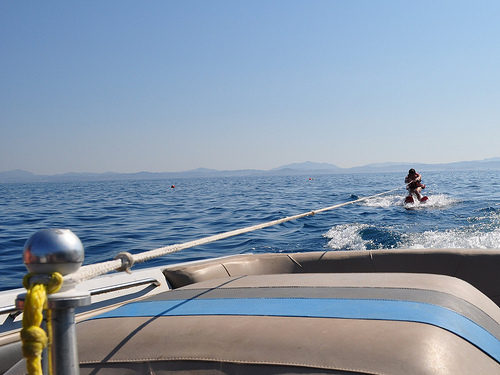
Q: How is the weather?
A: It is clear.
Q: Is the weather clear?
A: Yes, it is clear.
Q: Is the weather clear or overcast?
A: It is clear.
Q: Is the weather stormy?
A: No, it is clear.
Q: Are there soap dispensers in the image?
A: No, there are no soap dispensers.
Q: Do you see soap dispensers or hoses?
A: No, there are no soap dispensers or hoses.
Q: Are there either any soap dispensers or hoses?
A: No, there are no soap dispensers or hoses.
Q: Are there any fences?
A: No, there are no fences.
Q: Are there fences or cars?
A: No, there are no fences or cars.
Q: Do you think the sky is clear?
A: Yes, the sky is clear.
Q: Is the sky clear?
A: Yes, the sky is clear.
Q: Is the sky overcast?
A: No, the sky is clear.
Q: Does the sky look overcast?
A: No, the sky is clear.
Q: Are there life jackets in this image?
A: No, there are no life jackets.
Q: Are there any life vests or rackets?
A: No, there are no life vests or rackets.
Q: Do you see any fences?
A: No, there are no fences.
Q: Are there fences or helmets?
A: No, there are no fences or helmets.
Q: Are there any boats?
A: Yes, there is a boat.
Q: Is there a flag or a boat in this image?
A: Yes, there is a boat.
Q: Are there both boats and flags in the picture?
A: No, there is a boat but no flags.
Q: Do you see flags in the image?
A: No, there are no flags.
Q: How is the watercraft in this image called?
A: The watercraft is a boat.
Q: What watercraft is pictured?
A: The watercraft is a boat.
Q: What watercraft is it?
A: The watercraft is a boat.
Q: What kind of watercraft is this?
A: That is a boat.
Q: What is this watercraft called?
A: That is a boat.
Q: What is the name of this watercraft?
A: That is a boat.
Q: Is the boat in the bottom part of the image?
A: Yes, the boat is in the bottom of the image.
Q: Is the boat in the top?
A: No, the boat is in the bottom of the image.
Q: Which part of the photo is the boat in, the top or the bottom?
A: The boat is in the bottom of the image.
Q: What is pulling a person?
A: The boat is pulling a person.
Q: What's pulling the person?
A: The boat is pulling a person.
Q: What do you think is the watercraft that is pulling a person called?
A: The watercraft is a boat.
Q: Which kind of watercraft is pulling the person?
A: The watercraft is a boat.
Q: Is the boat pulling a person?
A: Yes, the boat is pulling a person.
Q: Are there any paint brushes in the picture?
A: No, there are no paint brushes.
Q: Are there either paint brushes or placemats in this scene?
A: No, there are no paint brushes or placemats.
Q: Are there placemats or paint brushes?
A: No, there are no paint brushes or placemats.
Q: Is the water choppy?
A: Yes, the water is choppy.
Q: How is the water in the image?
A: The water is choppy.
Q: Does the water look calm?
A: No, the water is choppy.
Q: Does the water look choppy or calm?
A: The water is choppy.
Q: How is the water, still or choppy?
A: The water is choppy.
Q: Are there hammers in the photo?
A: No, there are no hammers.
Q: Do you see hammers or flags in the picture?
A: No, there are no hammers or flags.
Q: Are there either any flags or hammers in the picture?
A: No, there are no hammers or flags.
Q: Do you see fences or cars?
A: No, there are no fences or cars.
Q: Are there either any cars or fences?
A: No, there are no fences or cars.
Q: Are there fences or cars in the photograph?
A: No, there are no fences or cars.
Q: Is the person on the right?
A: Yes, the person is on the right of the image.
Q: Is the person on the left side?
A: No, the person is on the right of the image.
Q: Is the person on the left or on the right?
A: The person is on the right of the image.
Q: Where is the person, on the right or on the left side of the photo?
A: The person is on the right of the image.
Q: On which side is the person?
A: The person is on the right of the image.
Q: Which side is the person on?
A: The person is on the right of the image.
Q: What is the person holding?
A: The person is holding the rope.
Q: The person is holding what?
A: The person is holding the rope.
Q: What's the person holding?
A: The person is holding the rope.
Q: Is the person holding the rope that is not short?
A: Yes, the person is holding the rope.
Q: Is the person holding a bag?
A: No, the person is holding the rope.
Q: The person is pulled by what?
A: The person is pulled by the boat.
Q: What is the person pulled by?
A: The person is pulled by the boat.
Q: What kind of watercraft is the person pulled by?
A: The person is pulled by the boat.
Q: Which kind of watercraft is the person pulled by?
A: The person is pulled by the boat.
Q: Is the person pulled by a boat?
A: Yes, the person is pulled by a boat.